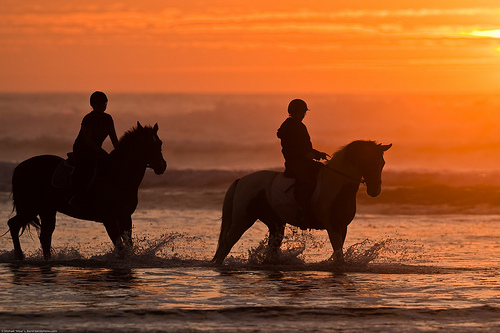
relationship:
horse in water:
[5, 120, 169, 267] [100, 240, 404, 323]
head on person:
[271, 103, 320, 131] [279, 100, 333, 170]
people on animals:
[66, 82, 382, 182] [53, 147, 464, 287]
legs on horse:
[183, 215, 377, 243] [252, 160, 447, 261]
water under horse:
[129, 238, 379, 313] [208, 131, 418, 261]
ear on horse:
[383, 137, 403, 158] [222, 147, 396, 281]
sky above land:
[122, 16, 361, 123] [73, 294, 453, 329]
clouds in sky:
[7, 7, 493, 60] [1, 3, 499, 90]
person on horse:
[275, 96, 333, 227] [219, 130, 389, 264]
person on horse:
[59, 79, 117, 182] [10, 122, 167, 267]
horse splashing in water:
[206, 138, 392, 272] [2, 86, 498, 322]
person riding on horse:
[70, 92, 116, 154] [10, 122, 167, 267]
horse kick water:
[204, 133, 393, 274] [224, 233, 404, 283]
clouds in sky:
[7, 7, 493, 60] [0, 0, 490, 164]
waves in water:
[152, 152, 488, 208] [2, 100, 497, 304]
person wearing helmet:
[275, 96, 333, 227] [285, 97, 311, 118]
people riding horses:
[72, 80, 329, 194] [13, 118, 398, 272]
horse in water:
[206, 138, 392, 272] [2, 144, 498, 329]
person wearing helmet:
[275, 96, 333, 227] [285, 93, 314, 115]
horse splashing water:
[206, 138, 392, 272] [2, 144, 498, 329]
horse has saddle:
[204, 133, 393, 274] [272, 165, 322, 206]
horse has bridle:
[221, 131, 394, 253] [352, 165, 395, 197]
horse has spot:
[204, 133, 393, 274] [326, 183, 356, 231]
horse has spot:
[204, 133, 393, 274] [240, 183, 286, 229]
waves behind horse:
[1, 145, 484, 212] [204, 133, 393, 274]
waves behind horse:
[1, 145, 484, 212] [7, 119, 176, 272]